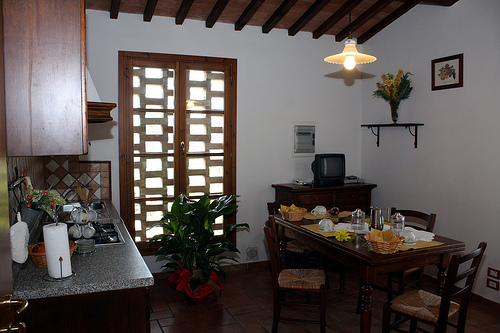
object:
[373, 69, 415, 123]
vase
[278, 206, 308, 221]
basket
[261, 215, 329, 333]
chair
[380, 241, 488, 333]
chair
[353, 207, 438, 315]
chair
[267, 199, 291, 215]
chair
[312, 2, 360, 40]
rafter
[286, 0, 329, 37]
rafter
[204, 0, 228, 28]
rafter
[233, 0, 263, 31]
rafter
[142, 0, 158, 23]
rafter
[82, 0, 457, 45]
ceiling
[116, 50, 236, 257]
window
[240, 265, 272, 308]
ground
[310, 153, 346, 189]
t.v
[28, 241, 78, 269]
basket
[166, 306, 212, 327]
floor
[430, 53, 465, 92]
picture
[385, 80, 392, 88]
flowers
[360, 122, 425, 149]
shelf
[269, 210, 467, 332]
table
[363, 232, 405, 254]
basket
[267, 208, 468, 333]
dining table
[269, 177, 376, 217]
stand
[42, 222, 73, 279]
paper towel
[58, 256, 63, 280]
holder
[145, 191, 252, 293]
plant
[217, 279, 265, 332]
floor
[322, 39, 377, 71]
light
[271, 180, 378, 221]
bureau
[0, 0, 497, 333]
room